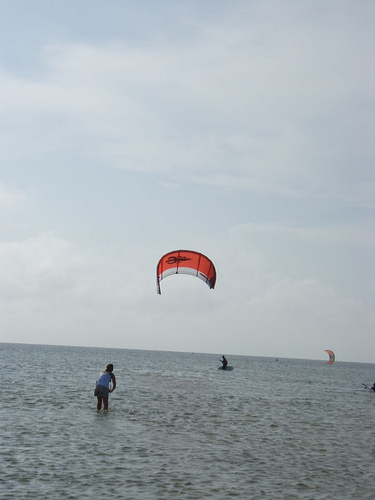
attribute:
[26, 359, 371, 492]
lake — shallow, choppy, large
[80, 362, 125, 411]
woman — wading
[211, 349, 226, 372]
man — kneeling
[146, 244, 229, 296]
parasail — white, red, grey, orange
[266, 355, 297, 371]
person — swimming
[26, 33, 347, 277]
sky — cloudy, blue, light blue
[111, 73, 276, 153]
clouds — grey, white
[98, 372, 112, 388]
top — white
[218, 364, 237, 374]
board — medium size, black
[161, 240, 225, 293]
kite — red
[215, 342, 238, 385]
person — standing, windsailing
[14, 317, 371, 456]
ocean — blue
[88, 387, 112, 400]
shorts — beige, khaki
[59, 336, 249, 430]
people — windsailing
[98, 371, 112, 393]
shirt — white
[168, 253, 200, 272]
design — black